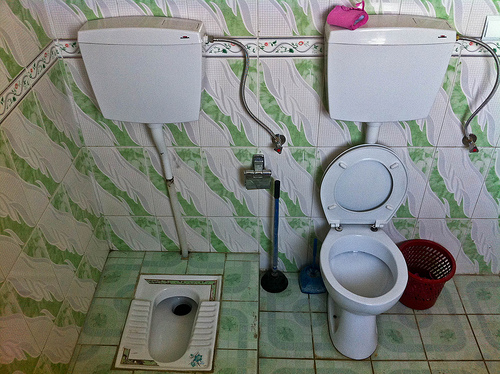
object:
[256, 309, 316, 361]
tile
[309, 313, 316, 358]
grout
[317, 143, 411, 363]
toilet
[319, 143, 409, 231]
lid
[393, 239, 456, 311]
basket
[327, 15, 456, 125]
tank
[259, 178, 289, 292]
plunger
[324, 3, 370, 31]
item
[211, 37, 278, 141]
pipe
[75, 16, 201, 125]
bathroom fixtures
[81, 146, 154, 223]
tile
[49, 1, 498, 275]
wall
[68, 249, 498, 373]
floor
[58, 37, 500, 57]
boarder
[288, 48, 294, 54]
flowers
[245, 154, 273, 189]
object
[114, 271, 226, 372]
urinal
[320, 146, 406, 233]
toilet seat